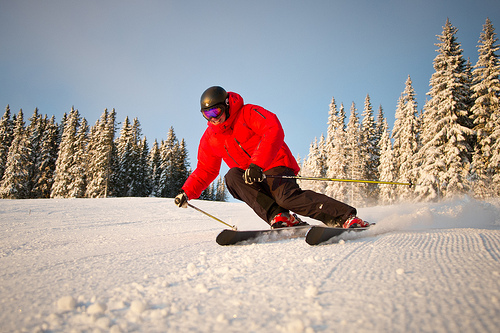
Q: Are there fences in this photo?
A: No, there are no fences.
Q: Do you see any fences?
A: No, there are no fences.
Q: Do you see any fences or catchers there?
A: No, there are no fences or catchers.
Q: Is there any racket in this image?
A: No, there are no rackets.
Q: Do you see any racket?
A: No, there are no rackets.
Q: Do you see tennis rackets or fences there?
A: No, there are no tennis rackets or fences.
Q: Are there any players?
A: No, there are no players.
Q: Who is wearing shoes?
A: The man is wearing shoes.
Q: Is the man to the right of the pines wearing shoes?
A: Yes, the man is wearing shoes.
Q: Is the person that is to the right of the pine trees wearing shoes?
A: Yes, the man is wearing shoes.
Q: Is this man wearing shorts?
A: No, the man is wearing shoes.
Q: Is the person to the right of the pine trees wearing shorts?
A: No, the man is wearing shoes.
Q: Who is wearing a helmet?
A: The man is wearing a helmet.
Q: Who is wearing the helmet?
A: The man is wearing a helmet.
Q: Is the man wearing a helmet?
A: Yes, the man is wearing a helmet.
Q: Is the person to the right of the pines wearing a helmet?
A: Yes, the man is wearing a helmet.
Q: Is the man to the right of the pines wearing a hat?
A: No, the man is wearing a helmet.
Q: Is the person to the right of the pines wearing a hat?
A: No, the man is wearing a helmet.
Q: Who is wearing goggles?
A: The man is wearing goggles.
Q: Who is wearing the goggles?
A: The man is wearing goggles.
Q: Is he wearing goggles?
A: Yes, the man is wearing goggles.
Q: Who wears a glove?
A: The man wears a glove.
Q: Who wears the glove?
A: The man wears a glove.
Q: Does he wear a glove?
A: Yes, the man wears a glove.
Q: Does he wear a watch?
A: No, the man wears a glove.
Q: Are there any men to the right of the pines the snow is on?
A: Yes, there is a man to the right of the pine trees.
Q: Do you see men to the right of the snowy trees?
A: Yes, there is a man to the right of the pine trees.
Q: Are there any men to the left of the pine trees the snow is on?
A: No, the man is to the right of the pine trees.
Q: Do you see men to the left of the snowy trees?
A: No, the man is to the right of the pine trees.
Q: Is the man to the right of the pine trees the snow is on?
A: Yes, the man is to the right of the pines.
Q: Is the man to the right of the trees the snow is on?
A: Yes, the man is to the right of the pines.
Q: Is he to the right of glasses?
A: No, the man is to the right of the pines.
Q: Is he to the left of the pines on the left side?
A: No, the man is to the right of the pine trees.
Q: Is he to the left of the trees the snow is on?
A: No, the man is to the right of the pine trees.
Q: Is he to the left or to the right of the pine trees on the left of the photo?
A: The man is to the right of the pine trees.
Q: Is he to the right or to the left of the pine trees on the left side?
A: The man is to the right of the pine trees.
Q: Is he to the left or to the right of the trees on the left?
A: The man is to the right of the pine trees.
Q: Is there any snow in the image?
A: Yes, there is snow.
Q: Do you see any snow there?
A: Yes, there is snow.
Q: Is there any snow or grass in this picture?
A: Yes, there is snow.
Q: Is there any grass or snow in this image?
A: Yes, there is snow.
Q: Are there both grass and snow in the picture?
A: No, there is snow but no grass.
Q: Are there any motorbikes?
A: No, there are no motorbikes.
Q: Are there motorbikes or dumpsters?
A: No, there are no motorbikes or dumpsters.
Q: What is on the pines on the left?
A: The snow is on the pine trees.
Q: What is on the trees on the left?
A: The snow is on the pine trees.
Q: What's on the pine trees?
A: The snow is on the pine trees.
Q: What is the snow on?
A: The snow is on the pine trees.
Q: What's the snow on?
A: The snow is on the pine trees.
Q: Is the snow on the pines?
A: Yes, the snow is on the pines.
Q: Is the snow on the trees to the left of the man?
A: Yes, the snow is on the pines.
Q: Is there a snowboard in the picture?
A: No, there are no snowboards.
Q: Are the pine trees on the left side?
A: Yes, the pine trees are on the left of the image.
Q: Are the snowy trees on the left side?
A: Yes, the pine trees are on the left of the image.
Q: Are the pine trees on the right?
A: No, the pine trees are on the left of the image.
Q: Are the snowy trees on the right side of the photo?
A: No, the pine trees are on the left of the image.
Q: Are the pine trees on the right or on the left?
A: The pine trees are on the left of the image.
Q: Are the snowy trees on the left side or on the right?
A: The pine trees are on the left of the image.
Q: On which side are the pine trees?
A: The pine trees are on the left of the image.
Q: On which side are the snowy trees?
A: The pine trees are on the left of the image.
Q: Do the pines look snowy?
A: Yes, the pines are snowy.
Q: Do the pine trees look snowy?
A: Yes, the pine trees are snowy.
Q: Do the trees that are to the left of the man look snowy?
A: Yes, the pine trees are snowy.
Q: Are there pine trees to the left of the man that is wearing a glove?
A: Yes, there are pine trees to the left of the man.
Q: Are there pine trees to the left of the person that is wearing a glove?
A: Yes, there are pine trees to the left of the man.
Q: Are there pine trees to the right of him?
A: No, the pine trees are to the left of the man.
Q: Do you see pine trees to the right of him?
A: No, the pine trees are to the left of the man.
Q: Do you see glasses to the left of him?
A: No, there are pine trees to the left of the man.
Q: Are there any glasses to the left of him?
A: No, there are pine trees to the left of the man.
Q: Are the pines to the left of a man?
A: Yes, the pines are to the left of a man.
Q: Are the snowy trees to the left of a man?
A: Yes, the pines are to the left of a man.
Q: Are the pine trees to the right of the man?
A: No, the pine trees are to the left of the man.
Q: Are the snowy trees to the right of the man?
A: No, the pine trees are to the left of the man.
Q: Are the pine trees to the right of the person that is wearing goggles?
A: No, the pine trees are to the left of the man.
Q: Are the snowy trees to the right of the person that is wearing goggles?
A: No, the pine trees are to the left of the man.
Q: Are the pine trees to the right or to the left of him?
A: The pine trees are to the left of the man.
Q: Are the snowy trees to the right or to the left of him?
A: The pine trees are to the left of the man.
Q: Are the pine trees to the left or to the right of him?
A: The pine trees are to the left of the man.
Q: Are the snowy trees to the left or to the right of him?
A: The pine trees are to the left of the man.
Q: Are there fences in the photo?
A: No, there are no fences.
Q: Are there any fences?
A: No, there are no fences.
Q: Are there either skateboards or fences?
A: No, there are no fences or skateboards.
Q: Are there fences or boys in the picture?
A: No, there are no fences or boys.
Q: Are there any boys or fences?
A: No, there are no fences or boys.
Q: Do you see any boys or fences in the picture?
A: No, there are no fences or boys.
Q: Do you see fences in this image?
A: No, there are no fences.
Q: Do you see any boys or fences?
A: No, there are no fences or boys.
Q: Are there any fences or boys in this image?
A: No, there are no fences or boys.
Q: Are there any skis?
A: Yes, there are skis.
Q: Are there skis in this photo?
A: Yes, there are skis.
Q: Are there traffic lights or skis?
A: Yes, there are skis.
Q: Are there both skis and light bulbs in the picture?
A: No, there are skis but no light bulbs.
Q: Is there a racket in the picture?
A: No, there are no rackets.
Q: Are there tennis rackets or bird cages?
A: No, there are no tennis rackets or bird cages.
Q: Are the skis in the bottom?
A: Yes, the skis are in the bottom of the image.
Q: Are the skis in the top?
A: No, the skis are in the bottom of the image.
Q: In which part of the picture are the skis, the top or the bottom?
A: The skis are in the bottom of the image.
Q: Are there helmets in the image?
A: Yes, there is a helmet.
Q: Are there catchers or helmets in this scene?
A: Yes, there is a helmet.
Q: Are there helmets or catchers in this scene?
A: Yes, there is a helmet.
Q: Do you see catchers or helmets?
A: Yes, there is a helmet.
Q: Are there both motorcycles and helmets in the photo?
A: No, there is a helmet but no motorcycles.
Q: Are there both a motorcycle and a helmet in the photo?
A: No, there is a helmet but no motorcycles.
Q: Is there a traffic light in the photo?
A: No, there are no traffic lights.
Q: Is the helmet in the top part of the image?
A: Yes, the helmet is in the top of the image.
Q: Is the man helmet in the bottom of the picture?
A: No, the helmet is in the top of the image.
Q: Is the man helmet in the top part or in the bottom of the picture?
A: The helmet is in the top of the image.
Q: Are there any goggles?
A: Yes, there are goggles.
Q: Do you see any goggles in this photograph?
A: Yes, there are goggles.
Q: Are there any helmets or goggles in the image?
A: Yes, there are goggles.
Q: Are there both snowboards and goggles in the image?
A: No, there are goggles but no snowboards.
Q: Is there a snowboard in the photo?
A: No, there are no snowboards.